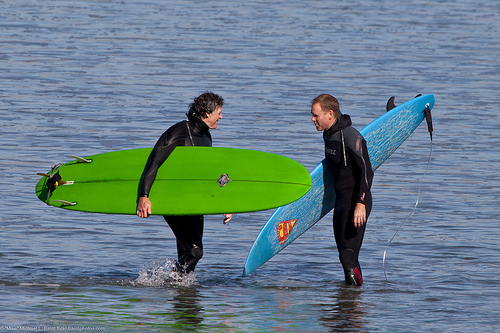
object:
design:
[275, 217, 297, 243]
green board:
[33, 146, 315, 216]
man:
[134, 90, 233, 280]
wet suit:
[136, 120, 230, 279]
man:
[321, 116, 374, 288]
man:
[310, 92, 373, 288]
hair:
[307, 93, 342, 120]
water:
[0, 0, 499, 333]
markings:
[352, 130, 367, 159]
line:
[381, 134, 433, 282]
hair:
[182, 89, 224, 120]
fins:
[420, 108, 434, 140]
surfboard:
[237, 84, 442, 296]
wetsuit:
[321, 120, 375, 286]